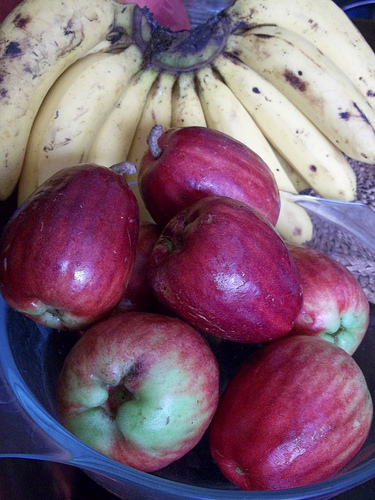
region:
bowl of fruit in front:
[0, 119, 359, 475]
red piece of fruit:
[146, 205, 287, 365]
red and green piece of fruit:
[69, 304, 206, 465]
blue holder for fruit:
[0, 304, 86, 439]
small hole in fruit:
[97, 350, 143, 429]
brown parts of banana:
[126, 1, 232, 78]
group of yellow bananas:
[1, 0, 337, 256]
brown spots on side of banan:
[0, 18, 81, 91]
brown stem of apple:
[135, 122, 169, 153]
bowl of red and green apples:
[30, 179, 368, 460]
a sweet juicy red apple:
[164, 199, 303, 329]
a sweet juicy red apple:
[224, 340, 360, 485]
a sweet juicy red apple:
[82, 325, 211, 463]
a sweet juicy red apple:
[12, 168, 125, 307]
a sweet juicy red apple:
[146, 126, 267, 201]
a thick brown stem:
[147, 125, 162, 151]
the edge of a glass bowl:
[39, 414, 73, 456]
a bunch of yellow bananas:
[15, 11, 364, 153]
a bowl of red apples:
[15, 174, 361, 492]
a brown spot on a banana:
[282, 64, 300, 87]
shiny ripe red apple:
[0, 163, 138, 330]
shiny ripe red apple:
[210, 335, 372, 489]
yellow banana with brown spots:
[223, 25, 373, 164]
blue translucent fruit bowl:
[0, 181, 374, 499]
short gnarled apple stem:
[146, 125, 163, 158]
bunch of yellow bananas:
[0, 0, 372, 245]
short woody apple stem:
[108, 161, 135, 176]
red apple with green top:
[56, 312, 218, 472]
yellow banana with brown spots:
[17, 45, 141, 207]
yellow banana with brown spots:
[195, 63, 313, 244]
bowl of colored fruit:
[20, 146, 320, 454]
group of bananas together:
[0, 0, 283, 228]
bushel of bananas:
[0, 0, 282, 238]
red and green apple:
[46, 324, 206, 472]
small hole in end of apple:
[96, 369, 158, 423]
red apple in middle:
[138, 191, 303, 341]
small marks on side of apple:
[187, 293, 221, 334]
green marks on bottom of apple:
[322, 308, 354, 345]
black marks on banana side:
[236, 33, 329, 104]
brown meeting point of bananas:
[114, 6, 236, 74]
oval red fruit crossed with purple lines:
[5, 123, 307, 345]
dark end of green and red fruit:
[62, 357, 202, 458]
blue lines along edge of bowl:
[0, 315, 368, 495]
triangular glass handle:
[285, 182, 369, 264]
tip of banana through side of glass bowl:
[275, 180, 311, 248]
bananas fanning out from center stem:
[6, 3, 369, 243]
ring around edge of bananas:
[122, 2, 231, 72]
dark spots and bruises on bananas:
[278, 56, 368, 137]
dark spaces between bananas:
[132, 64, 229, 90]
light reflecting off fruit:
[58, 250, 256, 303]